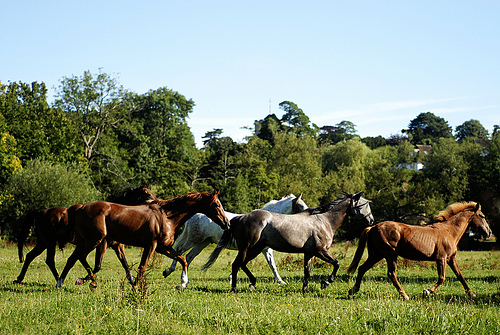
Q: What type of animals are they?
A: Horses.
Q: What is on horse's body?
A: Silvery sheen.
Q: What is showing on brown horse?
A: Ribs.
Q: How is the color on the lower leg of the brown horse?
A: White.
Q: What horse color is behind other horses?
A: White horse.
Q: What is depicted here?
A: Rear of horse behind same-color horse.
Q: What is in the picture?
A: Five horses.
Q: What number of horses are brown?
A: Three.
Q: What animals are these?
A: A herd of horses.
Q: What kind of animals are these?
A: Horses.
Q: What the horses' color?
A: White.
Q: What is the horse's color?
A: Gray.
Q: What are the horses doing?
A: Walking.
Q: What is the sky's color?
A: Blue.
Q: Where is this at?
A: Pasture.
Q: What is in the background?
A: Trees.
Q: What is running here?
A: Field.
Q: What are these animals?
A: Horses.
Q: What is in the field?
A: Horses.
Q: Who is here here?
A: Horses.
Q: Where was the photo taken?
A: In a field.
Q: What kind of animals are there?
A: Horses.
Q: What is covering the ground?
A: Grass.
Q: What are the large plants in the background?
A: Trees.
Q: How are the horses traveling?
A: By running.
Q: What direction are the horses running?
A: To the right.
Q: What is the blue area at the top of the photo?
A: The sky.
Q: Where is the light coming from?
A: The sun.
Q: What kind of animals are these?
A: Horses.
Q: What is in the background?
A: Trees.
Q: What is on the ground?
A: Grass.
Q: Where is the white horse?
A: In the back.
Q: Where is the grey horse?
A: In the middle.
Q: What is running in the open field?
A: Horses.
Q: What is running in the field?
A: Horses.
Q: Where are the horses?
A: Running in the field.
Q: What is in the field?
A: A variety of horses.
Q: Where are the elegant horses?
A: In an open field.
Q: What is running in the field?
A: Horses.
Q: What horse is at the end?
A: The dark brown horse.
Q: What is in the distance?
A: Green trees.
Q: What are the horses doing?
A: Running.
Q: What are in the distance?
A: Trees.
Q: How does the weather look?
A: Clear.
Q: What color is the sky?
A: Blue.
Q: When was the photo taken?
A: Yesterday.